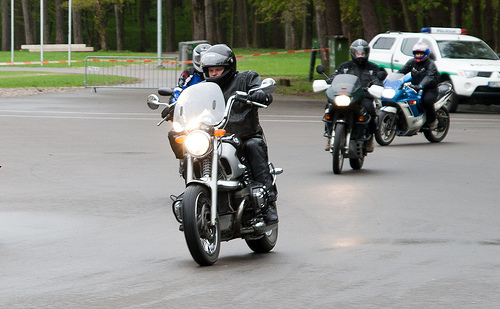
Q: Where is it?
A: This is at the street.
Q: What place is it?
A: It is a street.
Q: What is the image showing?
A: It is showing a street.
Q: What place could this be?
A: It is a street.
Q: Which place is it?
A: It is a street.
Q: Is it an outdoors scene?
A: Yes, it is outdoors.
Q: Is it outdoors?
A: Yes, it is outdoors.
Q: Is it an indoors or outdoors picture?
A: It is outdoors.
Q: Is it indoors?
A: No, it is outdoors.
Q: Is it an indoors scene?
A: No, it is outdoors.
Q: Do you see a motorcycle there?
A: Yes, there is a motorcycle.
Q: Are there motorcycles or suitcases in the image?
A: Yes, there is a motorcycle.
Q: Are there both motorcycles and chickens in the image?
A: No, there is a motorcycle but no chickens.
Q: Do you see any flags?
A: No, there are no flags.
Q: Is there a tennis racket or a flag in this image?
A: No, there are no flags or rackets.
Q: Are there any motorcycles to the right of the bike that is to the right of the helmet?
A: Yes, there is a motorcycle to the right of the bike.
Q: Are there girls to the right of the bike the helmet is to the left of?
A: No, there is a motorcycle to the right of the bike.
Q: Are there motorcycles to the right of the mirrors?
A: Yes, there is a motorcycle to the right of the mirrors.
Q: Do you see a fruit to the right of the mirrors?
A: No, there is a motorcycle to the right of the mirrors.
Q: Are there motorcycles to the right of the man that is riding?
A: Yes, there is a motorcycle to the right of the man.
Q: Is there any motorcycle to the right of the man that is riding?
A: Yes, there is a motorcycle to the right of the man.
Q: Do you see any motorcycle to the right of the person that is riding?
A: Yes, there is a motorcycle to the right of the man.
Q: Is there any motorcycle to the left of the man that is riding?
A: No, the motorcycle is to the right of the man.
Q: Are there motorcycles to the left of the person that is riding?
A: No, the motorcycle is to the right of the man.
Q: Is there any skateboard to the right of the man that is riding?
A: No, there is a motorcycle to the right of the man.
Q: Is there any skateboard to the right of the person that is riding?
A: No, there is a motorcycle to the right of the man.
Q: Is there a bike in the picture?
A: Yes, there is a bike.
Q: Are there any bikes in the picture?
A: Yes, there is a bike.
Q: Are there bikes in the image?
A: Yes, there is a bike.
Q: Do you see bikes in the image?
A: Yes, there is a bike.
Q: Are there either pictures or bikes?
A: Yes, there is a bike.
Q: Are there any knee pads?
A: No, there are no knee pads.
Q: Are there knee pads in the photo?
A: No, there are no knee pads.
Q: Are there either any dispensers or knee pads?
A: No, there are no knee pads or dispensers.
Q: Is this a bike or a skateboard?
A: This is a bike.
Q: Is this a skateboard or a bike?
A: This is a bike.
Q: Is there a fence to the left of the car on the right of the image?
A: No, there is a bike to the left of the car.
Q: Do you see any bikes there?
A: Yes, there is a bike.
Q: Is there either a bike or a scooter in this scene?
A: Yes, there is a bike.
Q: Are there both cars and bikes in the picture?
A: Yes, there are both a bike and a car.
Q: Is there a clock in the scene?
A: No, there are no clocks.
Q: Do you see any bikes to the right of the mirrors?
A: Yes, there is a bike to the right of the mirrors.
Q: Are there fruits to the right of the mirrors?
A: No, there is a bike to the right of the mirrors.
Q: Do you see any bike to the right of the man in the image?
A: Yes, there is a bike to the right of the man.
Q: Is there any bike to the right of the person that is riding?
A: Yes, there is a bike to the right of the man.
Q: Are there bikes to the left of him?
A: No, the bike is to the right of the man.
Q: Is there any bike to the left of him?
A: No, the bike is to the right of the man.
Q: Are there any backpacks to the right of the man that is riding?
A: No, there is a bike to the right of the man.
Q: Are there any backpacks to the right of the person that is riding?
A: No, there is a bike to the right of the man.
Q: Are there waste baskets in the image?
A: No, there are no waste baskets.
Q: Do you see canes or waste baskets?
A: No, there are no waste baskets or canes.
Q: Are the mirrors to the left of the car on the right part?
A: Yes, the mirrors are to the left of the car.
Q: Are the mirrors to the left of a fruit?
A: No, the mirrors are to the left of the car.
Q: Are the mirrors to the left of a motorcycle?
A: Yes, the mirrors are to the left of a motorcycle.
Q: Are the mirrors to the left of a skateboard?
A: No, the mirrors are to the left of a motorcycle.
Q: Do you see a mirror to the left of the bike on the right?
A: Yes, there are mirrors to the left of the bike.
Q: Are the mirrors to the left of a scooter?
A: No, the mirrors are to the left of a motorcycle.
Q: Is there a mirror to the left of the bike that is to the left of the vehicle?
A: Yes, there are mirrors to the left of the bike.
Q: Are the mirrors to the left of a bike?
A: Yes, the mirrors are to the left of a bike.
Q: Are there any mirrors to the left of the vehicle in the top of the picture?
A: Yes, there are mirrors to the left of the vehicle.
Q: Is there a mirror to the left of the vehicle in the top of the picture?
A: Yes, there are mirrors to the left of the vehicle.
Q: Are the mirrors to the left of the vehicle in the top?
A: Yes, the mirrors are to the left of the vehicle.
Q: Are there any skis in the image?
A: No, there are no skis.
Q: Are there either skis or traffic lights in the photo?
A: No, there are no skis or traffic lights.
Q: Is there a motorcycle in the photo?
A: Yes, there is a motorcycle.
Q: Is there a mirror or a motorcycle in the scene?
A: Yes, there is a motorcycle.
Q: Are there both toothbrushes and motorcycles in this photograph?
A: No, there is a motorcycle but no toothbrushes.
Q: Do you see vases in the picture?
A: No, there are no vases.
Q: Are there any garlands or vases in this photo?
A: No, there are no vases or garlands.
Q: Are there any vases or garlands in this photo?
A: No, there are no vases or garlands.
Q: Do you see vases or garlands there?
A: No, there are no vases or garlands.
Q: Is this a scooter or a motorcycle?
A: This is a motorcycle.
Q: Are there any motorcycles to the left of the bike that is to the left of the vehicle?
A: Yes, there is a motorcycle to the left of the bike.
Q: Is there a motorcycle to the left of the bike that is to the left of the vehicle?
A: Yes, there is a motorcycle to the left of the bike.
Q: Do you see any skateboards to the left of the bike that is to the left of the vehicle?
A: No, there is a motorcycle to the left of the bike.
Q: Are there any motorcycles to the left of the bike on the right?
A: Yes, there is a motorcycle to the left of the bike.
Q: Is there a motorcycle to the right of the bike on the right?
A: No, the motorcycle is to the left of the bike.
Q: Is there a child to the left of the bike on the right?
A: No, there is a motorcycle to the left of the bike.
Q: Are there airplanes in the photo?
A: No, there are no airplanes.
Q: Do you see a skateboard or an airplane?
A: No, there are no airplanes or skateboards.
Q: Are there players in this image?
A: No, there are no players.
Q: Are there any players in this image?
A: No, there are no players.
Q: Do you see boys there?
A: No, there are no boys.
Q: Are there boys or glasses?
A: No, there are no boys or glasses.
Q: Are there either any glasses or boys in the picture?
A: No, there are no boys or glasses.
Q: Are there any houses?
A: No, there are no houses.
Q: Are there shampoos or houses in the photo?
A: No, there are no houses or shampoos.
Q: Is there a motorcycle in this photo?
A: Yes, there is a motorcycle.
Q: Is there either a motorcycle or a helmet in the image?
A: Yes, there is a motorcycle.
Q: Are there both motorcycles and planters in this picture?
A: No, there is a motorcycle but no planters.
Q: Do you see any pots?
A: No, there are no pots.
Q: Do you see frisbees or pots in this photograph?
A: No, there are no pots or frisbees.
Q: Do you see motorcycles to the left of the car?
A: Yes, there is a motorcycle to the left of the car.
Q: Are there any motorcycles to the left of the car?
A: Yes, there is a motorcycle to the left of the car.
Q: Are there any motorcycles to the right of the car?
A: No, the motorcycle is to the left of the car.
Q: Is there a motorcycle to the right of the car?
A: No, the motorcycle is to the left of the car.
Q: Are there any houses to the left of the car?
A: No, there is a motorcycle to the left of the car.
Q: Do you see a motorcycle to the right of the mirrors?
A: Yes, there is a motorcycle to the right of the mirrors.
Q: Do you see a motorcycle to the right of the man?
A: Yes, there is a motorcycle to the right of the man.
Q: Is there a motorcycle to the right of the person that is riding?
A: Yes, there is a motorcycle to the right of the man.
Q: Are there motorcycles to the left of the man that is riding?
A: No, the motorcycle is to the right of the man.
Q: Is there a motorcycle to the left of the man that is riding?
A: No, the motorcycle is to the right of the man.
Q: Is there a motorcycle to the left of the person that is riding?
A: No, the motorcycle is to the right of the man.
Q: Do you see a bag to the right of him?
A: No, there is a motorcycle to the right of the man.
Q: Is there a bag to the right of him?
A: No, there is a motorcycle to the right of the man.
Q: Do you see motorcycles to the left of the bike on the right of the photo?
A: Yes, there is a motorcycle to the left of the bike.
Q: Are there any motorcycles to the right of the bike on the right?
A: No, the motorcycle is to the left of the bike.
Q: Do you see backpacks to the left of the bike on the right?
A: No, there is a motorcycle to the left of the bike.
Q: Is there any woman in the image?
A: No, there are no women.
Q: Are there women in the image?
A: No, there are no women.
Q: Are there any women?
A: No, there are no women.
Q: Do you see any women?
A: No, there are no women.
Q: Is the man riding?
A: Yes, the man is riding.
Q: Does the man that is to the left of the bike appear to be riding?
A: Yes, the man is riding.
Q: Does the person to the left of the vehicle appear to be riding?
A: Yes, the man is riding.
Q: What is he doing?
A: The man is riding.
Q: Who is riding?
A: The man is riding.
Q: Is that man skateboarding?
A: No, the man is riding.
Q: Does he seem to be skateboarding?
A: No, the man is riding.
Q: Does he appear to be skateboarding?
A: No, the man is riding.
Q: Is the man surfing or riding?
A: The man is riding.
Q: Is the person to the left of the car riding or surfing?
A: The man is riding.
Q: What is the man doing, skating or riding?
A: The man is riding.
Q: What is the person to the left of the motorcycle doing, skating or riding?
A: The man is riding.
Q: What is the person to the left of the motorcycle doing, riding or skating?
A: The man is riding.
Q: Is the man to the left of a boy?
A: No, the man is to the left of the motorcycle.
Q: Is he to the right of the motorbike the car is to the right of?
A: No, the man is to the left of the motorbike.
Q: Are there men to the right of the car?
A: No, the man is to the left of the car.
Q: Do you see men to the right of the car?
A: No, the man is to the left of the car.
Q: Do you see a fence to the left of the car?
A: No, there is a man to the left of the car.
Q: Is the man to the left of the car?
A: Yes, the man is to the left of the car.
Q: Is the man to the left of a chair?
A: No, the man is to the left of the car.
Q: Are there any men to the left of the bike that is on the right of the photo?
A: Yes, there is a man to the left of the bike.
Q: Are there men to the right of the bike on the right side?
A: No, the man is to the left of the bike.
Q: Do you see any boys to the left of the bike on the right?
A: No, there is a man to the left of the bike.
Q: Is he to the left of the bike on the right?
A: Yes, the man is to the left of the bike.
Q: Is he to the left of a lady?
A: No, the man is to the left of the bike.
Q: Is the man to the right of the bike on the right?
A: No, the man is to the left of the bike.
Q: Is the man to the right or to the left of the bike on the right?
A: The man is to the left of the bike.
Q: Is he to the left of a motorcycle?
A: Yes, the man is to the left of a motorcycle.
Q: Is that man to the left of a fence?
A: No, the man is to the left of a motorcycle.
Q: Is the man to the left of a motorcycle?
A: Yes, the man is to the left of a motorcycle.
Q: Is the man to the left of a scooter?
A: No, the man is to the left of a motorcycle.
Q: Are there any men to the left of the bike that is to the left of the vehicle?
A: Yes, there is a man to the left of the bike.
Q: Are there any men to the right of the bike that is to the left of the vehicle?
A: No, the man is to the left of the bike.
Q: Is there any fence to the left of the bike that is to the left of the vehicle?
A: No, there is a man to the left of the bike.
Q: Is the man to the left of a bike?
A: Yes, the man is to the left of a bike.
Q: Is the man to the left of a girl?
A: No, the man is to the left of a bike.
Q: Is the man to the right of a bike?
A: No, the man is to the left of a bike.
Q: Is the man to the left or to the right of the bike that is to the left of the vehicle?
A: The man is to the left of the bike.